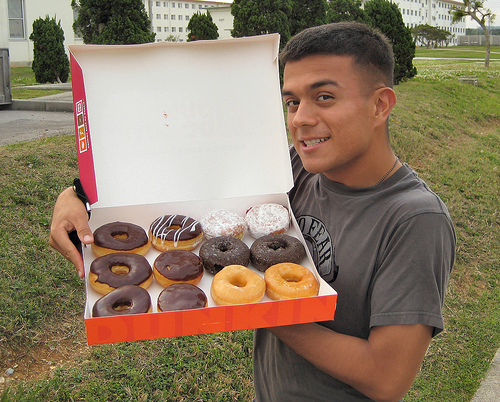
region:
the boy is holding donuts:
[36, 17, 448, 369]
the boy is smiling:
[265, 6, 415, 166]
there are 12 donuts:
[75, 204, 330, 336]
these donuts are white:
[196, 195, 288, 239]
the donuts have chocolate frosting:
[84, 205, 146, 312]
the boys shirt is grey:
[239, 152, 461, 375]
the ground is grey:
[3, 104, 60, 139]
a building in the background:
[383, 0, 470, 55]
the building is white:
[360, 0, 470, 67]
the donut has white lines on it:
[139, 202, 200, 245]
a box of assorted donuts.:
[48, 28, 355, 335]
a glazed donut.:
[261, 256, 328, 308]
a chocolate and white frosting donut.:
[145, 206, 210, 253]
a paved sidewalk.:
[461, 348, 498, 398]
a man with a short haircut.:
[274, 13, 418, 195]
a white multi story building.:
[342, 0, 469, 60]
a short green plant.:
[21, 3, 71, 82]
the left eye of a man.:
[300, 76, 342, 121]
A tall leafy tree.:
[447, 1, 498, 68]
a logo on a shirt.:
[282, 188, 360, 295]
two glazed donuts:
[210, 264, 310, 298]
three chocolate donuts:
[90, 225, 137, 332]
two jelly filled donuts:
[198, 206, 282, 235]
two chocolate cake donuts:
[199, 238, 296, 267]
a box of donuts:
[58, 34, 339, 349]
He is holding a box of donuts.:
[35, 22, 454, 389]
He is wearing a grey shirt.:
[280, 139, 414, 396]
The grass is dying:
[404, 77, 496, 214]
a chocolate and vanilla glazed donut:
[150, 213, 199, 246]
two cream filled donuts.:
[153, 246, 206, 313]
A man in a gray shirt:
[241, 7, 456, 395]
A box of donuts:
[55, 200, 330, 335]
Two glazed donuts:
[206, 260, 321, 300]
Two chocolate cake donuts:
[196, 227, 301, 267]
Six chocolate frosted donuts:
[90, 207, 205, 332]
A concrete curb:
[10, 90, 80, 120]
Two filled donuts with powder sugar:
[200, 195, 290, 241]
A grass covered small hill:
[390, 71, 490, 201]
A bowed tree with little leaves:
[445, 1, 495, 66]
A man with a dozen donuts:
[47, 24, 459, 371]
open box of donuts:
[56, 21, 338, 349]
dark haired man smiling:
[278, 6, 412, 197]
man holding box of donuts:
[44, 14, 458, 400]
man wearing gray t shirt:
[281, 11, 455, 395]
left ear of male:
[369, 81, 398, 133]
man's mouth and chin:
[295, 131, 337, 176]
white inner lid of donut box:
[66, 28, 298, 205]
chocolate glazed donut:
[86, 248, 153, 292]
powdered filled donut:
[198, 203, 246, 240]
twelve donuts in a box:
[88, 200, 324, 317]